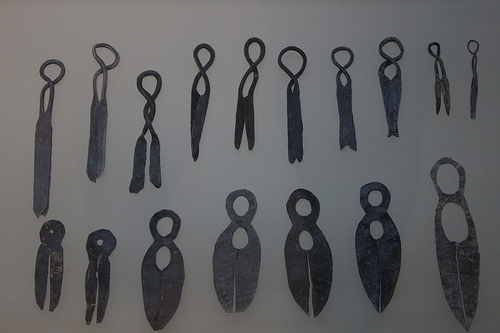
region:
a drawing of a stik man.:
[218, 32, 275, 144]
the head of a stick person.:
[217, 183, 263, 228]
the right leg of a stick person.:
[204, 263, 243, 328]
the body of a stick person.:
[290, 223, 323, 263]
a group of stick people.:
[27, 149, 487, 331]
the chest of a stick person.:
[140, 240, 188, 282]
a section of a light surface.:
[223, 155, 261, 168]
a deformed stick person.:
[73, 225, 123, 331]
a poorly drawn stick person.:
[74, 32, 129, 179]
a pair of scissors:
[27, 39, 68, 214]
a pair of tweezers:
[25, 223, 80, 315]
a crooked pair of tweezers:
[67, 197, 118, 329]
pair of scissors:
[132, 53, 174, 196]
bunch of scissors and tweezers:
[27, 11, 496, 327]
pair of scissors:
[363, 26, 410, 148]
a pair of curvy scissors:
[217, 21, 274, 161]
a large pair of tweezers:
[412, 153, 496, 332]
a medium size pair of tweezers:
[342, 171, 422, 320]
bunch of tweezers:
[2, 156, 464, 331]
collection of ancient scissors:
[21, 33, 494, 332]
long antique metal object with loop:
[29, 52, 70, 221]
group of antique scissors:
[23, 29, 490, 331]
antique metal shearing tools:
[24, 30, 486, 331]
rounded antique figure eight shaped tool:
[204, 183, 270, 320]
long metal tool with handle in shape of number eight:
[425, 150, 491, 332]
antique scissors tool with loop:
[276, 45, 311, 167]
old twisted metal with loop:
[127, 65, 172, 196]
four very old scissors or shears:
[26, 39, 123, 327]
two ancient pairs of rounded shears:
[281, 177, 404, 317]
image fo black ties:
[0, 30, 497, 319]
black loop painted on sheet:
[32, 56, 68, 90]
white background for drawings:
[115, 10, 187, 60]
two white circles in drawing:
[274, 182, 329, 257]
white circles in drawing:
[220, 186, 264, 255]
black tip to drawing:
[132, 270, 183, 331]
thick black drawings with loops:
[208, 150, 487, 327]